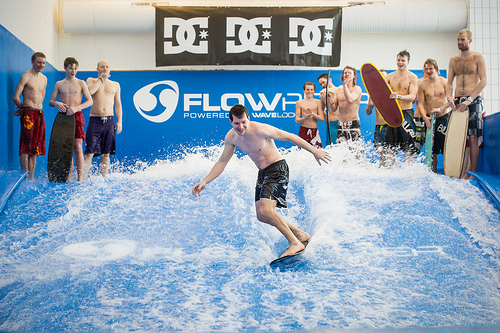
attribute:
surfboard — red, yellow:
[360, 62, 404, 127]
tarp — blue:
[0, 171, 15, 188]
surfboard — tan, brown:
[444, 104, 471, 180]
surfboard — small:
[267, 234, 310, 266]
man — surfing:
[191, 106, 332, 255]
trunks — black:
[234, 161, 299, 211]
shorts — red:
[73, 109, 85, 140]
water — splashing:
[344, 132, 392, 160]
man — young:
[48, 53, 101, 194]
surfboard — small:
[46, 109, 83, 181]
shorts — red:
[76, 110, 89, 142]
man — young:
[10, 48, 54, 183]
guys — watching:
[15, 51, 122, 182]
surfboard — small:
[253, 231, 335, 296]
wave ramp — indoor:
[107, 177, 420, 277]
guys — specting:
[300, 41, 487, 128]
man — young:
[86, 62, 121, 180]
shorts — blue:
[85, 112, 117, 157]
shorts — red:
[16, 100, 48, 160]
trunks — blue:
[86, 115, 116, 155]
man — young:
[55, 57, 86, 178]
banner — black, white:
[147, 9, 345, 69]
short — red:
[17, 101, 52, 158]